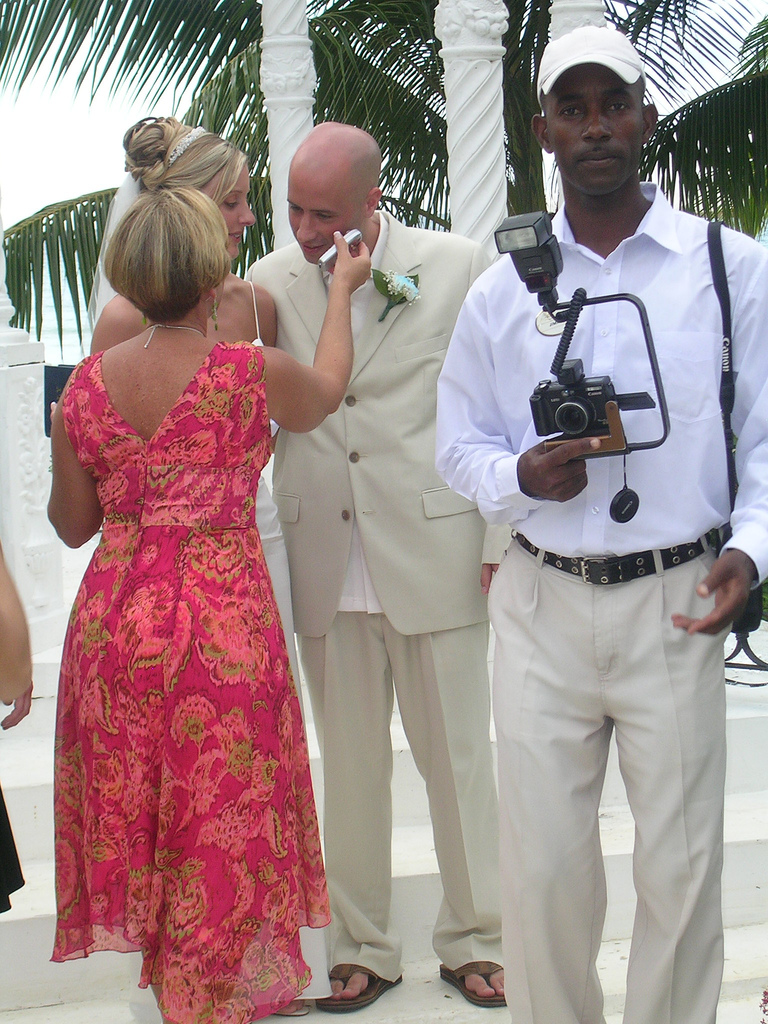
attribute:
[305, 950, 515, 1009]
slippers — brown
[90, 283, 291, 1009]
dress — white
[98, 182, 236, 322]
hair — blonde, short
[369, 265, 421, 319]
flower — white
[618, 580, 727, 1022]
pant leg — wrinkled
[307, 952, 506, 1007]
sandles — brown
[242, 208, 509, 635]
jacket — cream-colored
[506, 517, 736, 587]
belt — black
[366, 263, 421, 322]
flower — blue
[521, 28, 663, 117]
cap — white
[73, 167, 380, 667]
woman — blonde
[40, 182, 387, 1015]
woman — blonde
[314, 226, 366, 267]
cellphone — silver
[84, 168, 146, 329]
veil — white